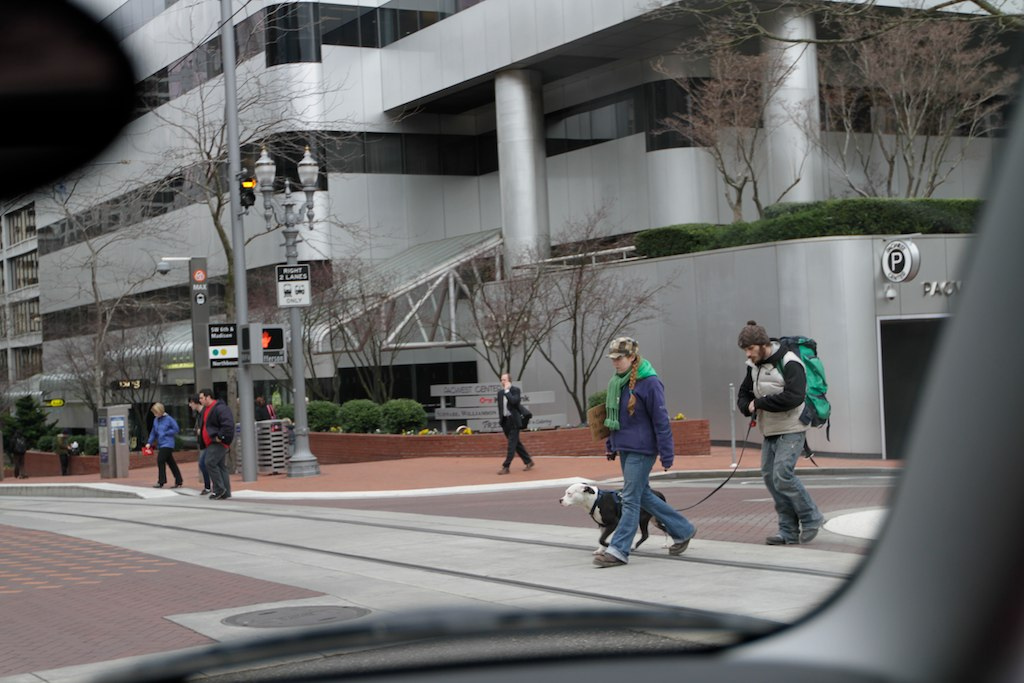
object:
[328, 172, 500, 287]
wall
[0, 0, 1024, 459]
building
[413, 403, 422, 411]
leaves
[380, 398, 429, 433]
tree